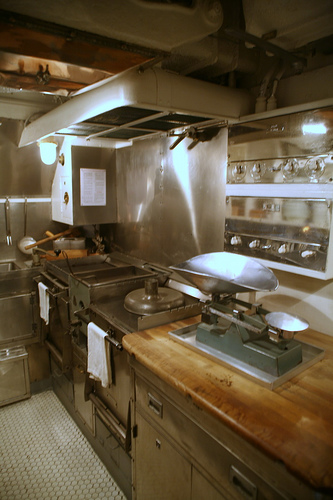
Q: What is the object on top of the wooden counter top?
A: Scale.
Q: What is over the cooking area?
A: Huge vent.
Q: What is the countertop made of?
A: Wood.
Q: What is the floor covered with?
A: Tiny white tiles.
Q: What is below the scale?
A: A wooden counter.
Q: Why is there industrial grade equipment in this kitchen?
A: The kitchen is in a restaurant.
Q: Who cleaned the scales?
A: Kitchen crew.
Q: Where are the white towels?
A: On two of the oven handles?.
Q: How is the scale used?
A: To measure ingredients.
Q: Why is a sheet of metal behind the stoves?
A: For safety.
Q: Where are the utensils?
A: In the back on the left.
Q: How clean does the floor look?
A: Not very.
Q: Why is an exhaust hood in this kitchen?
A: To vent fumes from the stove.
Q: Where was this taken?
A: Kitchen.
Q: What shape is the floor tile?
A: Octagons.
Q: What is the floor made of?
A: Tile.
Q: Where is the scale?
A: On the counter.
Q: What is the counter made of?
A: Wood.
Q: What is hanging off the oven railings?
A: Towels.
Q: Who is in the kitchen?
A: No body.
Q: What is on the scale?
A: Nothing.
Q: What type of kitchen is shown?
A: Restaurant kitchen.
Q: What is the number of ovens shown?
A: 2.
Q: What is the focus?
A: Professional kitchen.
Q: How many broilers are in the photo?
A: 2.